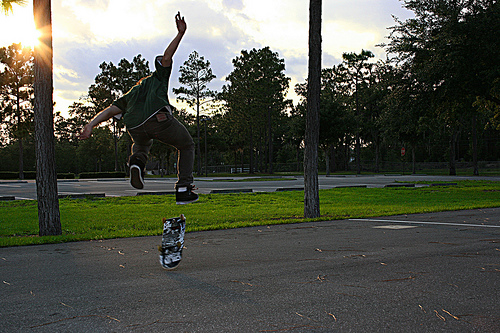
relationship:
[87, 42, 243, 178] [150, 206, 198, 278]
man jumping on skateboards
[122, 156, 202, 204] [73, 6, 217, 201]
shoes on man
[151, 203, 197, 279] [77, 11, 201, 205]
skateboard under boy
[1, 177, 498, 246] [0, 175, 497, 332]
median in parking lot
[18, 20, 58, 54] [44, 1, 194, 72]
sun shining through clouds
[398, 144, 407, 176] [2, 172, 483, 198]
stop sign behind parking lot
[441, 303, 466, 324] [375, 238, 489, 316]
sticks on asphalt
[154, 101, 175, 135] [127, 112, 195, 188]
tag on jeans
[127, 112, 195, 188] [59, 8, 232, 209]
jeans on boy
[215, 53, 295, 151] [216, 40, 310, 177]
tree with leaves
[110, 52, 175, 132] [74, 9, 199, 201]
shirt on man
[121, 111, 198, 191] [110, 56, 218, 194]
jeans on man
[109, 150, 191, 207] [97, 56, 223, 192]
shoes on man